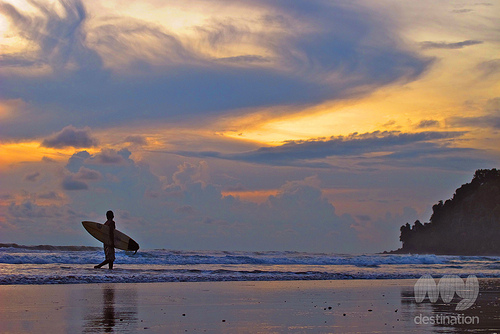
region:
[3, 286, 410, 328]
Wet and sandy beach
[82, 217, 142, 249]
Surfboard being carried by person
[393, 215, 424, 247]
silhouetted trees on a hillside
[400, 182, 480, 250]
stone hillside with trees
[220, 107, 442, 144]
Sunlight shining through the clouds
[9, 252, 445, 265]
Small ocean wave coming into shore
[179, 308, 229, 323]
Rocks washed onto the beach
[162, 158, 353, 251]
Fluffy cumulus clouds in evening sky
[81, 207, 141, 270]
Man carrying surfboard while walking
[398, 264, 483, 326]
Name of organization responsible for picture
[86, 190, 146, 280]
man at the beach walking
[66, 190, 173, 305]
man at the beach walking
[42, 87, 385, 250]
gray, orange clouds in the sky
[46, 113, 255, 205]
gray, orange clouds in the sky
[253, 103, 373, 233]
gray, orange clouds in the sky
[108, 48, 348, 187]
gray, orange clouds in the sky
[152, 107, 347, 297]
gray, orange clouds in the sky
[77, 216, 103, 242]
a surfboard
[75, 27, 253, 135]
clouds in the sky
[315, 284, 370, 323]
rocks on the sand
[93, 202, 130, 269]
a person walking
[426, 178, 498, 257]
a rock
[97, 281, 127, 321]
a shadow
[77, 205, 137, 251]
man carrying a surfboard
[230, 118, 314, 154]
the sun is bright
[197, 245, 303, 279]
the ocean water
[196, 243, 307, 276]
the water is blue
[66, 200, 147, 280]
a man carrying a surfboard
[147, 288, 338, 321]
wet sand of the beach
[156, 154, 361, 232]
fluffly white clouds in the sky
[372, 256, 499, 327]
logo of the photographer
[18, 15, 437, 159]
orange cloudy skies over the ocean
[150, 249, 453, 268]
a wave rolling in toward the beach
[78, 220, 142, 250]
white black and yellow surf board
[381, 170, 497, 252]
trees growing on a hillside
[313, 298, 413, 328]
several small rocks on the beach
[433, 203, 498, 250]
rock cliffside next to the ocean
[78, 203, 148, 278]
person carrying a surfboard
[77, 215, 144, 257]
surfboard near the water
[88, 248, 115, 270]
leg of a person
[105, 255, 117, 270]
leg of a person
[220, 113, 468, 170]
white cloud in the sky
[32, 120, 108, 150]
white cloud in the sky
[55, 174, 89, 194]
white cloud in the sky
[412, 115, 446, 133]
white cloud in the sky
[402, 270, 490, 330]
watermark on a photo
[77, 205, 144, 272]
person walking with surfboard